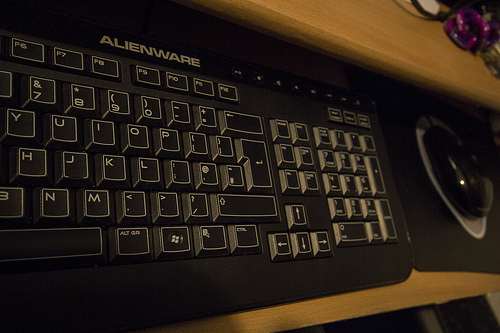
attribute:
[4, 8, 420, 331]
keyboard — black, white outlined, white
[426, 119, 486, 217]
mouse — black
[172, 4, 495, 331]
computer table — brown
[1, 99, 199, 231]
letters — white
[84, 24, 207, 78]
brand name — Alienware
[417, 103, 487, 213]
mouse — black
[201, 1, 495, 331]
table — brown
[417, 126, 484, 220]
mouse — black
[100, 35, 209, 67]
word — white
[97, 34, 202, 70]
letters — upper case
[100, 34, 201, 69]
alienware logo — typographic